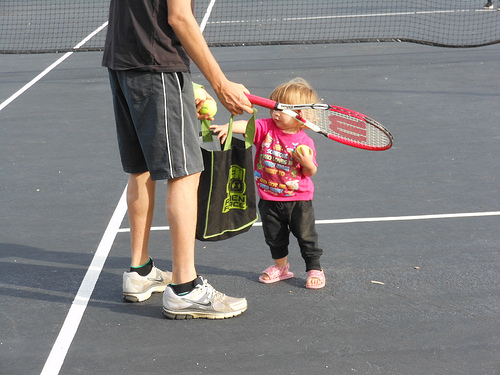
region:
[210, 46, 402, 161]
A man holding a bat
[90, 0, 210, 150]
A man wearing black color shirt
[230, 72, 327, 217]
A kid wearing pink color shirt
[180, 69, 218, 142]
A man holding two balls on his other hand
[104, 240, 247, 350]
White color shoes on the mans feet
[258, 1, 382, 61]
Tennies net infront of the man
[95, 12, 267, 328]
Man holding a bag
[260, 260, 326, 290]
Pink color chappel on the kids leg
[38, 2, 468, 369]
A man and a kid standing in a tennis court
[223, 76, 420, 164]
Red and white color bat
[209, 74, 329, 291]
A child holding a tennis ball.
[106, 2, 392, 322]
A person holding a tennis racket.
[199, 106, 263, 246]
A bag being held by a man.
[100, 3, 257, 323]
A man wearing sneakers on feet.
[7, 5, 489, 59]
A net surrounding a tennis field?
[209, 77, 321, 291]
A child with blonde hair.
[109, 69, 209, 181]
Black shorts on a man.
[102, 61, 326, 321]
A man and child standing in a tennis court field.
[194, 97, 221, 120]
A tennis ball on the man's left hand?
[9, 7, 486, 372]
A tennis court with white lines on ground.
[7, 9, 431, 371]
picture taken outside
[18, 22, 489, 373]
picture taken during the day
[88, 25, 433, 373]
a girl with her dad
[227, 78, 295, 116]
the man is holding a tennis racket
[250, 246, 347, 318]
the man wears shoes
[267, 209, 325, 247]
the baby wears black pants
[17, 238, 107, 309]
the shadow of the man and baby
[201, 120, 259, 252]
the man holds a bag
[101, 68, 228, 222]
the man wears shorts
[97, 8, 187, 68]
the man wears a black shirt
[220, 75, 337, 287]
little girl wearing pink shirt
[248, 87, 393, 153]
pink, white, and black tennis racket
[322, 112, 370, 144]
pink W on white racket strings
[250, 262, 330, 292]
pink shoes of little girl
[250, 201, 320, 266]
black pants of young girl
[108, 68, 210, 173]
black shorts with white piping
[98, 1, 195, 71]
black shirt of the man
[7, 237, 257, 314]
shadows of child and man on tennis court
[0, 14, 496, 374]
white lines on the tennis court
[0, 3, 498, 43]
black tennis net on the court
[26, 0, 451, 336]
photograph taken at a tennis court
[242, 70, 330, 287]
small child reaching into bag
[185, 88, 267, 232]
black fabric bag with green handles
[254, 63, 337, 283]
small child with blond hair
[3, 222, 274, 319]
shadow of people on tennis court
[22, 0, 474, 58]
black tennis netting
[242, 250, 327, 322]
girl wearing pink shoes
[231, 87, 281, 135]
red handle of tennis racket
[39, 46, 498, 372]
white lines on tennis court to create boundaries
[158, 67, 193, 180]
white stripes on mans shorts